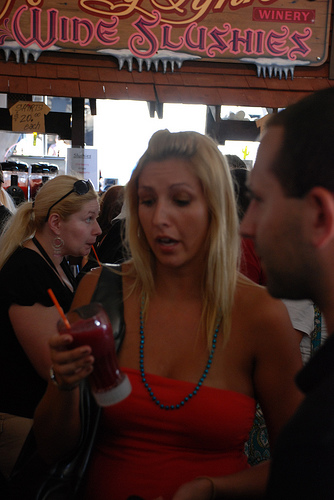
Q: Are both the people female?
A: Yes, all the people are female.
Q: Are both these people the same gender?
A: Yes, all the people are female.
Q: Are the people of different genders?
A: No, all the people are female.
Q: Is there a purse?
A: Yes, there is a purse.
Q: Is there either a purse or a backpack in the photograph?
A: Yes, there is a purse.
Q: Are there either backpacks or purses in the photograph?
A: Yes, there is a purse.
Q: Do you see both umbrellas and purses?
A: No, there is a purse but no umbrellas.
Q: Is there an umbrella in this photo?
A: No, there are no umbrellas.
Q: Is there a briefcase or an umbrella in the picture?
A: No, there are no umbrellas or briefcases.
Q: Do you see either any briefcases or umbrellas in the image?
A: No, there are no umbrellas or briefcases.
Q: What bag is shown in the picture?
A: The bag is a purse.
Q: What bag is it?
A: The bag is a purse.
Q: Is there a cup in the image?
A: Yes, there is a cup.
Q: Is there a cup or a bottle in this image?
A: Yes, there is a cup.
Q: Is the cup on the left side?
A: Yes, the cup is on the left of the image.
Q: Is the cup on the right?
A: No, the cup is on the left of the image.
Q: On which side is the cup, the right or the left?
A: The cup is on the left of the image.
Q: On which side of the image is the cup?
A: The cup is on the left of the image.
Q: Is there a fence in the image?
A: No, there are no fences.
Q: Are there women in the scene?
A: Yes, there is a woman.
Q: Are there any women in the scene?
A: Yes, there is a woman.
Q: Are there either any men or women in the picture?
A: Yes, there is a woman.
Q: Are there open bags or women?
A: Yes, there is an open woman.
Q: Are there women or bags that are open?
A: Yes, the woman is open.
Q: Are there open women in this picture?
A: Yes, there is an open woman.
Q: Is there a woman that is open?
A: Yes, there is a woman that is open.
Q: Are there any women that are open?
A: Yes, there is a woman that is open.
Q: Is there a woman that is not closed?
A: Yes, there is a open woman.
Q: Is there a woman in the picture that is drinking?
A: Yes, there is a woman that is drinking.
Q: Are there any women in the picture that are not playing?
A: Yes, there is a woman that is drinking.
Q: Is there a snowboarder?
A: No, there are no snowboarders.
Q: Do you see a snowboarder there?
A: No, there are no snowboarders.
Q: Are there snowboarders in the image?
A: No, there are no snowboarders.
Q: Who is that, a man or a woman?
A: That is a woman.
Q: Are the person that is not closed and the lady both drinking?
A: Yes, both the woman and the lady are drinking.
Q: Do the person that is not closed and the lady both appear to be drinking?
A: Yes, both the woman and the lady are drinking.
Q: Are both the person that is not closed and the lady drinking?
A: Yes, both the woman and the lady are drinking.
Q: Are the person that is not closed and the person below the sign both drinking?
A: Yes, both the woman and the lady are drinking.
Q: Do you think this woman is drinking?
A: Yes, the woman is drinking.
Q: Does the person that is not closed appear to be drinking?
A: Yes, the woman is drinking.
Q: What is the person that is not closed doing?
A: The woman is drinking.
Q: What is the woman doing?
A: The woman is drinking.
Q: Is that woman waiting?
A: No, the woman is drinking.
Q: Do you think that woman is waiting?
A: No, the woman is drinking.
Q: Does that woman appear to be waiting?
A: No, the woman is drinking.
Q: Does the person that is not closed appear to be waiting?
A: No, the woman is drinking.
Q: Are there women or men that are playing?
A: No, there is a woman but she is drinking.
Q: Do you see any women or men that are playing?
A: No, there is a woman but she is drinking.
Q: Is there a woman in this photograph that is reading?
A: No, there is a woman but she is drinking.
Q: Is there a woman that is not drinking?
A: No, there is a woman but she is drinking.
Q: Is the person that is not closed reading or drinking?
A: The woman is drinking.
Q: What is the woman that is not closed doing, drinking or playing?
A: The woman is drinking.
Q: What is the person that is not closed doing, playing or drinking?
A: The woman is drinking.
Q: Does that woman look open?
A: Yes, the woman is open.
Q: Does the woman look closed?
A: No, the woman is open.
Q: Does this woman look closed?
A: No, the woman is open.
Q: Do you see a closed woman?
A: No, there is a woman but she is open.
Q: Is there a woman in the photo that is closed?
A: No, there is a woman but she is open.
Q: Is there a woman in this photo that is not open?
A: No, there is a woman but she is open.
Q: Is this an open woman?
A: Yes, this is an open woman.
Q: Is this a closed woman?
A: No, this is an open woman.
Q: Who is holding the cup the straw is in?
A: The woman is holding the cup.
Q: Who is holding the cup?
A: The woman is holding the cup.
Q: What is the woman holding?
A: The woman is holding the cup.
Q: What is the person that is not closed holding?
A: The woman is holding the cup.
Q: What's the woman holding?
A: The woman is holding the cup.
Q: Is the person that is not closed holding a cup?
A: Yes, the woman is holding a cup.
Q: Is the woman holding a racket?
A: No, the woman is holding a cup.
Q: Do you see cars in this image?
A: No, there are no cars.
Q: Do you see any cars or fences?
A: No, there are no cars or fences.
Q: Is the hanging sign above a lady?
A: Yes, the sign is above a lady.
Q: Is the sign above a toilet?
A: No, the sign is above a lady.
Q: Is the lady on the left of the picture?
A: Yes, the lady is on the left of the image.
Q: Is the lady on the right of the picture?
A: No, the lady is on the left of the image.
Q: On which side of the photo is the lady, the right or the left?
A: The lady is on the left of the image.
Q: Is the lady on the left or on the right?
A: The lady is on the left of the image.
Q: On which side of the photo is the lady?
A: The lady is on the left of the image.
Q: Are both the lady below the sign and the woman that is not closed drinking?
A: Yes, both the lady and the woman are drinking.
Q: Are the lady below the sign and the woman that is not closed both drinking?
A: Yes, both the lady and the woman are drinking.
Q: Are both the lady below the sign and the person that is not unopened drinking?
A: Yes, both the lady and the woman are drinking.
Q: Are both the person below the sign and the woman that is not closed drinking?
A: Yes, both the lady and the woman are drinking.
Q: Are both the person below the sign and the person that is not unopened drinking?
A: Yes, both the lady and the woman are drinking.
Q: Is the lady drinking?
A: Yes, the lady is drinking.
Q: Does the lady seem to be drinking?
A: Yes, the lady is drinking.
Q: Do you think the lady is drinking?
A: Yes, the lady is drinking.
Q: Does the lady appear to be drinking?
A: Yes, the lady is drinking.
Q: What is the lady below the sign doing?
A: The lady is drinking.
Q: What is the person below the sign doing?
A: The lady is drinking.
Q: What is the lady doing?
A: The lady is drinking.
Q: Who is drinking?
A: The lady is drinking.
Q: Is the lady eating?
A: No, the lady is drinking.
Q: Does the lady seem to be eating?
A: No, the lady is drinking.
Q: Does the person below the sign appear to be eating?
A: No, the lady is drinking.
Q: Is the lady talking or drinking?
A: The lady is drinking.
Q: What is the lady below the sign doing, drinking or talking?
A: The lady is drinking.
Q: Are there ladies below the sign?
A: Yes, there is a lady below the sign.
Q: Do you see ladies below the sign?
A: Yes, there is a lady below the sign.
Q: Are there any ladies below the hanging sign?
A: Yes, there is a lady below the sign.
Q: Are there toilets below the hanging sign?
A: No, there is a lady below the sign.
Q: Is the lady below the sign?
A: Yes, the lady is below the sign.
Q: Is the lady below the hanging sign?
A: Yes, the lady is below the sign.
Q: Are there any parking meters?
A: No, there are no parking meters.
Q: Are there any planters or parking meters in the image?
A: No, there are no parking meters or planters.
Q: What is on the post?
A: The paper is on the post.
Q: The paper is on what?
A: The paper is on the post.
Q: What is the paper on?
A: The paper is on the post.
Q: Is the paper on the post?
A: Yes, the paper is on the post.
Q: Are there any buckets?
A: No, there are no buckets.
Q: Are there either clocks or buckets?
A: No, there are no buckets or clocks.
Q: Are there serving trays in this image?
A: No, there are no serving trays.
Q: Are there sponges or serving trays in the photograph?
A: No, there are no serving trays or sponges.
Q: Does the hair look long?
A: Yes, the hair is long.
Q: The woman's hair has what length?
A: The hair is long.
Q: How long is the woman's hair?
A: The hair is long.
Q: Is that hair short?
A: No, the hair is long.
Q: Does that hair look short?
A: No, the hair is long.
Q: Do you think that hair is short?
A: No, the hair is long.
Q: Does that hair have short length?
A: No, the hair is long.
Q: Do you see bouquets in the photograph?
A: No, there are no bouquets.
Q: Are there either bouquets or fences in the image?
A: No, there are no bouquets or fences.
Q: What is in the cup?
A: The straw is in the cup.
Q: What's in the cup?
A: The straw is in the cup.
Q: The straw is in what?
A: The straw is in the cup.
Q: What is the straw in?
A: The straw is in the cup.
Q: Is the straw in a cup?
A: Yes, the straw is in a cup.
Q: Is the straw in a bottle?
A: No, the straw is in a cup.